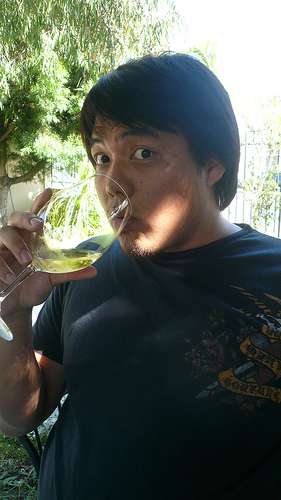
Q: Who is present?
A: A man.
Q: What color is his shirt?
A: Black.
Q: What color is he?
A: White.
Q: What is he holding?
A: A glass.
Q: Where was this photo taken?
A: Near a tree.